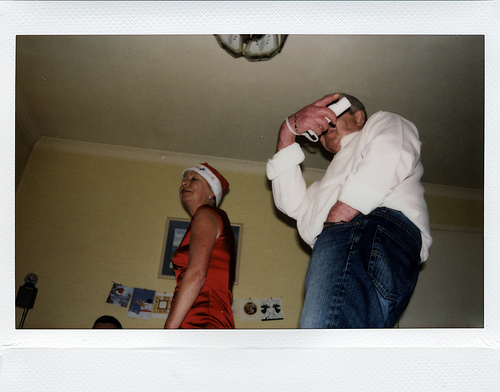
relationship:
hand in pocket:
[325, 199, 373, 225] [314, 214, 369, 271]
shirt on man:
[262, 110, 432, 261] [266, 90, 434, 326]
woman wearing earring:
[171, 163, 233, 330] [207, 190, 215, 200]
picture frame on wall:
[158, 217, 244, 285] [17, 132, 483, 329]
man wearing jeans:
[266, 90, 434, 326] [296, 206, 422, 327]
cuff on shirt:
[258, 130, 313, 192] [255, 104, 460, 254]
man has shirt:
[266, 90, 434, 326] [262, 110, 432, 261]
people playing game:
[139, 153, 291, 343] [315, 86, 353, 127]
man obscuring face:
[266, 90, 434, 326] [319, 110, 357, 149]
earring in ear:
[201, 188, 223, 210] [343, 92, 372, 136]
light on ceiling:
[211, 30, 293, 64] [40, 32, 233, 134]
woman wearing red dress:
[155, 162, 240, 334] [176, 210, 243, 334]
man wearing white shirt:
[278, 94, 465, 369] [254, 109, 436, 257]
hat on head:
[185, 160, 229, 202] [168, 147, 256, 212]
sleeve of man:
[266, 151, 324, 232] [261, 60, 428, 349]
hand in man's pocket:
[320, 200, 361, 227] [313, 213, 360, 254]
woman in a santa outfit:
[155, 162, 240, 334] [161, 152, 238, 330]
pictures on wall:
[94, 269, 274, 329] [86, 220, 157, 321]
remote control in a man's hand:
[288, 91, 343, 137] [284, 91, 341, 136]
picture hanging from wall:
[153, 207, 248, 287] [17, 132, 483, 329]